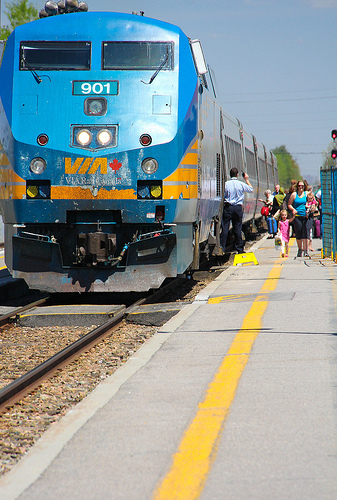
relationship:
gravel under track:
[0, 322, 160, 467] [1, 291, 152, 408]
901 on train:
[81, 82, 110, 96] [2, 13, 278, 294]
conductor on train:
[217, 168, 255, 252] [2, 13, 278, 294]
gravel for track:
[0, 322, 160, 467] [1, 291, 152, 408]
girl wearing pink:
[276, 210, 298, 260] [280, 222, 290, 236]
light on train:
[75, 127, 112, 148] [2, 13, 278, 294]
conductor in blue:
[217, 168, 255, 252] [228, 187, 239, 214]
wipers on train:
[19, 57, 42, 86] [2, 13, 278, 294]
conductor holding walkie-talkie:
[217, 168, 255, 252] [239, 169, 249, 180]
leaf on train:
[109, 160, 123, 176] [2, 13, 278, 294]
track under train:
[1, 291, 152, 408] [2, 13, 278, 294]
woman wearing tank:
[289, 181, 313, 258] [291, 190, 307, 217]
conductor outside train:
[217, 168, 255, 252] [2, 13, 278, 294]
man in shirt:
[217, 168, 255, 252] [225, 178, 256, 209]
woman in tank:
[289, 181, 313, 258] [291, 190, 307, 217]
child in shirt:
[276, 210, 298, 260] [276, 219, 292, 244]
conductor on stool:
[217, 168, 255, 252] [233, 251, 258, 268]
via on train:
[63, 155, 109, 178] [2, 13, 278, 294]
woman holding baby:
[289, 181, 313, 258] [308, 196, 318, 214]